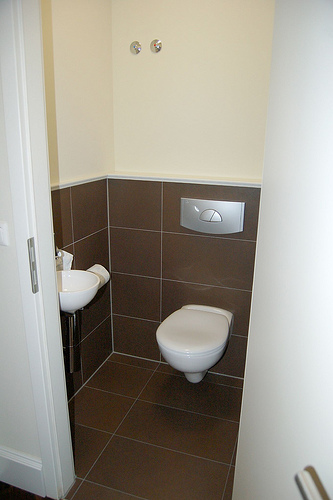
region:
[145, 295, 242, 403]
this is a toilet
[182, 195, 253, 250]
this is a soap dispenser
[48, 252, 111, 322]
this is a sink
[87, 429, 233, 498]
this is a tile in the bathroom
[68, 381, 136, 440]
this is a tile in the bathroom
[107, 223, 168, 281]
this is a tile in the bathroom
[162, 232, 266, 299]
this is a tile in the bathroom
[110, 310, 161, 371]
this is a tile in the bathroom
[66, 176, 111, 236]
this is a tile in the bathroom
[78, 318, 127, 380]
this is a tile in the bathroom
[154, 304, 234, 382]
white toilet in a bathroom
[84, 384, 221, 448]
brown bathroom tile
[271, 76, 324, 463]
white bathroom door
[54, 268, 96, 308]
white round bathroom sink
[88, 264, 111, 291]
roll of white toilet tissue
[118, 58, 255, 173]
beige bathroom wall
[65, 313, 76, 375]
silver pipe under the bathroom sink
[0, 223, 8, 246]
white lightswitch outside of the bathroom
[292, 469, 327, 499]
silver doorknob on the bathroom door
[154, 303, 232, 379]
toilet with the lid down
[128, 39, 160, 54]
a red and green pair of knobs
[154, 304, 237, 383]
a white porcelain toilet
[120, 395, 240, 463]
a brown tile floor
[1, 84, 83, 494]
a white doorway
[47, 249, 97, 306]
a bowl like sink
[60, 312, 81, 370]
metallic piping beneath a sink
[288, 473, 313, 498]
a metal door handle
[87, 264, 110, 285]
a roll of toilet paper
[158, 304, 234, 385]
a white toilet seat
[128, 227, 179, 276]
the wall is made of tile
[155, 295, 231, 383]
the toilet is white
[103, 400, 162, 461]
the floor is brown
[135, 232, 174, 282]
the wall is brown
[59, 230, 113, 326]
the urinal is white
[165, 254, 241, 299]
the reflection is on the wall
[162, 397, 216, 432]
the shadow is on the floor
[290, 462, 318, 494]
the bar is white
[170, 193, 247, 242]
the button is gray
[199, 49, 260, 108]
the upper wall is tan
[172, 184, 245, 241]
Silver paper dispenser over toilet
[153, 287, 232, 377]
Toilet bowl over the floor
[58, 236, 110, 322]
Sink in the bathroom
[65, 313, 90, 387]
Drain pipe in the bathroom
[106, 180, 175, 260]
Brown tile on the bathroom wall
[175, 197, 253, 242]
Silver dispenser in the bathroom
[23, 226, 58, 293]
Silver handle on the door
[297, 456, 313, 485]
Chrome door handle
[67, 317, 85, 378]
Silver drain pipe under sink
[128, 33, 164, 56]
Red and Blue button on the wall